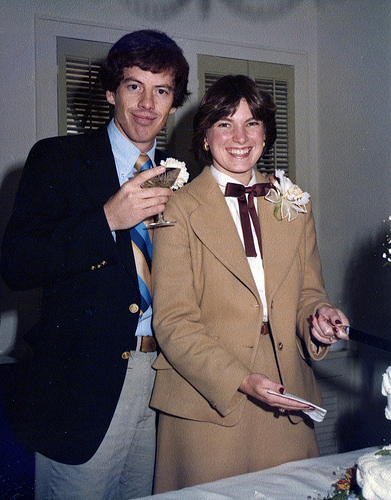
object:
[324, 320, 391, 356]
fork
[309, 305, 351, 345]
hand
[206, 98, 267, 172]
woman's face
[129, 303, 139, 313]
button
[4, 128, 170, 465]
jacket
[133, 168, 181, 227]
champagne glass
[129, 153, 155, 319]
tie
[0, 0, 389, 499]
photo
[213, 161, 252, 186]
neck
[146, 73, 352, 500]
woman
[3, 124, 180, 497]
suit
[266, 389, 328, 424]
handkerchief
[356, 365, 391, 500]
white cake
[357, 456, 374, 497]
edge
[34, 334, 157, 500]
slacks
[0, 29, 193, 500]
man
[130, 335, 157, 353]
belt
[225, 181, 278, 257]
bow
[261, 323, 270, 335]
belt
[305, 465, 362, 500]
flowers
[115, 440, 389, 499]
table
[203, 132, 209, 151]
ear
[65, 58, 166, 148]
shutters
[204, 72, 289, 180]
shutters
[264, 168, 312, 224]
flower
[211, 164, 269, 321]
shirt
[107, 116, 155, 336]
shirt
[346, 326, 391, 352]
blade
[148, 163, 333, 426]
jacket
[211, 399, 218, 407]
button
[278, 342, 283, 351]
button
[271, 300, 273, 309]
button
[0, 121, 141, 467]
blazer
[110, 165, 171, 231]
hand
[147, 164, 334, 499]
dress suit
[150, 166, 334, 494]
suit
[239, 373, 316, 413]
hand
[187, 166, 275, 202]
collar